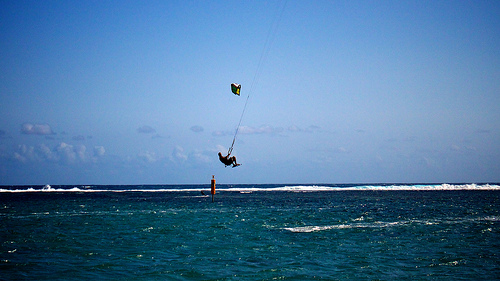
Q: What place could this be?
A: It is an ocean.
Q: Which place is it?
A: It is an ocean.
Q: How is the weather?
A: It is cloudy.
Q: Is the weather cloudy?
A: Yes, it is cloudy.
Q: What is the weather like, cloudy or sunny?
A: It is cloudy.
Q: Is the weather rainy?
A: No, it is cloudy.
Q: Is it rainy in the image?
A: No, it is cloudy.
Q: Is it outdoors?
A: Yes, it is outdoors.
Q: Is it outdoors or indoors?
A: It is outdoors.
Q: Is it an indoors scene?
A: No, it is outdoors.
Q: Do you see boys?
A: No, there are no boys.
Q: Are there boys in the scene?
A: No, there are no boys.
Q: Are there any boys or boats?
A: No, there are no boys or boats.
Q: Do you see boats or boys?
A: No, there are no boys or boats.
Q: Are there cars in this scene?
A: No, there are no cars.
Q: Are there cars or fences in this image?
A: No, there are no cars or fences.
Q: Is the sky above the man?
A: Yes, the sky is above the man.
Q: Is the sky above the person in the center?
A: Yes, the sky is above the man.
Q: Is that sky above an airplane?
A: No, the sky is above the man.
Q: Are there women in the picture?
A: No, there are no women.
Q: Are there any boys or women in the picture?
A: No, there are no women or boys.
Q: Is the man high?
A: Yes, the man is high.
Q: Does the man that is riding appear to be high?
A: Yes, the man is high.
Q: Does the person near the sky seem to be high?
A: Yes, the man is high.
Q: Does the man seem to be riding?
A: Yes, the man is riding.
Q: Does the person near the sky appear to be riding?
A: Yes, the man is riding.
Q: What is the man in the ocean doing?
A: The man is riding.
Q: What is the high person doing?
A: The man is riding.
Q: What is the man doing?
A: The man is riding.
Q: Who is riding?
A: The man is riding.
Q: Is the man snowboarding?
A: No, the man is riding.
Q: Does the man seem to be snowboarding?
A: No, the man is riding.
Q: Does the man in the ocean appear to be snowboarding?
A: No, the man is riding.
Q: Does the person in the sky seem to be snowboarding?
A: No, the man is riding.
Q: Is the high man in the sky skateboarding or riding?
A: The man is riding.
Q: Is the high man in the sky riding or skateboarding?
A: The man is riding.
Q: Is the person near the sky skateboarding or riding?
A: The man is riding.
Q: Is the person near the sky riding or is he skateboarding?
A: The man is riding.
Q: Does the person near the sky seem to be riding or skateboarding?
A: The man is riding.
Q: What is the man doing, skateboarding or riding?
A: The man is riding.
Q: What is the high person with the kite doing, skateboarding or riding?
A: The man is riding.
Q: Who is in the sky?
A: The man is in the sky.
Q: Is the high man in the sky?
A: Yes, the man is in the sky.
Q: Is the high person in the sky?
A: Yes, the man is in the sky.